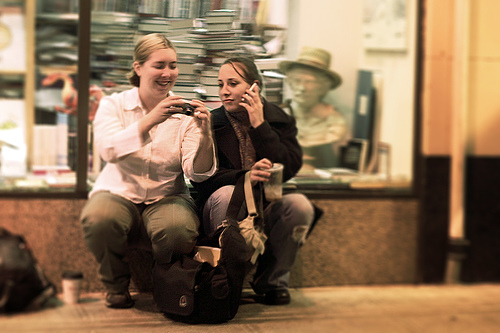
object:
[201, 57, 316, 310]
woman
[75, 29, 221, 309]
woman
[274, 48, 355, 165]
bust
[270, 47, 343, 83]
hat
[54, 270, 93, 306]
coffe cup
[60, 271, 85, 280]
lid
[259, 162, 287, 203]
cup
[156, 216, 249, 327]
bag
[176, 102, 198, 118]
camera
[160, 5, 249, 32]
books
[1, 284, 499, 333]
sidewalk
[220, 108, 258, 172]
scarf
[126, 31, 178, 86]
hair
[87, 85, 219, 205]
shirt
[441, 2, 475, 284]
pole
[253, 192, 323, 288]
leg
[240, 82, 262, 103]
cellphone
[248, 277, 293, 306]
shoe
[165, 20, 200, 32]
book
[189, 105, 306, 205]
jacket